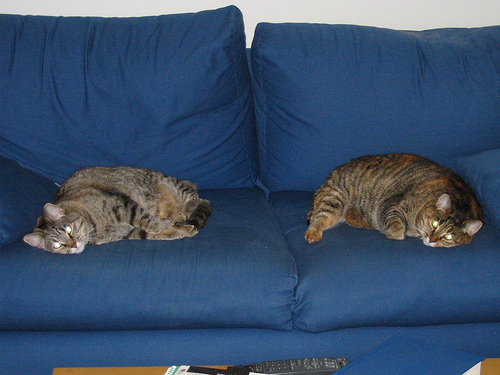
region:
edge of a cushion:
[226, 105, 251, 159]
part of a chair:
[208, 275, 256, 340]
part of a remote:
[273, 354, 285, 369]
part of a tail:
[192, 191, 214, 233]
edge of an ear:
[42, 191, 63, 210]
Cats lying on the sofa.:
[27, 133, 486, 295]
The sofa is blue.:
[213, 230, 386, 309]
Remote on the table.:
[233, 345, 353, 373]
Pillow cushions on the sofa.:
[18, 20, 499, 164]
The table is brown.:
[60, 365, 202, 373]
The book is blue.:
[343, 331, 474, 373]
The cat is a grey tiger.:
[16, 152, 208, 259]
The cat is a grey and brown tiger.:
[301, 147, 486, 258]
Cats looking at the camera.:
[21, 132, 488, 271]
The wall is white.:
[0, 0, 498, 25]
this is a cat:
[304, 137, 474, 269]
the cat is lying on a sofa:
[308, 149, 486, 256]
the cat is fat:
[366, 164, 403, 204]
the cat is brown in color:
[386, 160, 415, 192]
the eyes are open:
[429, 215, 453, 239]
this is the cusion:
[326, 252, 391, 315]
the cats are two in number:
[38, 128, 460, 263]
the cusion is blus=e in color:
[321, 257, 376, 324]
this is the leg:
[302, 217, 328, 241]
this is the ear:
[46, 200, 63, 217]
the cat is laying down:
[278, 105, 498, 280]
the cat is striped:
[281, 100, 480, 266]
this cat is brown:
[302, 95, 488, 270]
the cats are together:
[10, 107, 486, 287]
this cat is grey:
[7, 132, 280, 264]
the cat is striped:
[23, 101, 309, 361]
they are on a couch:
[25, 13, 491, 303]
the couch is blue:
[23, 57, 455, 270]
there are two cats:
[31, 47, 496, 342]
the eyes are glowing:
[410, 197, 467, 267]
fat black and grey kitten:
[18, 156, 219, 265]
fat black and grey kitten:
[284, 165, 498, 267]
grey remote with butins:
[234, 339, 357, 374]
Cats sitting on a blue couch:
[17, 38, 498, 373]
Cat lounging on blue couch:
[278, 88, 476, 315]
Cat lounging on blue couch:
[10, 93, 234, 283]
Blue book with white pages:
[353, 338, 498, 373]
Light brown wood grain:
[50, 368, 138, 373]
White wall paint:
[292, 3, 422, 23]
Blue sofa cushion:
[17, 0, 292, 150]